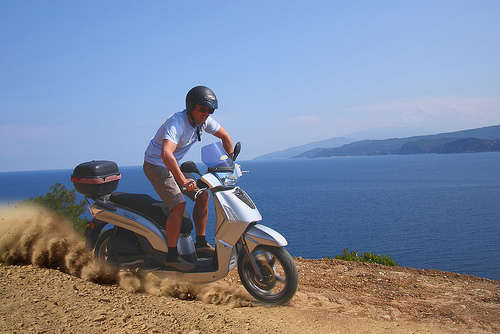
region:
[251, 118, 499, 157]
Mountains next to water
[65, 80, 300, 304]
Man riding a silver scooter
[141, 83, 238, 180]
Man with black helmet wearing a blue shirt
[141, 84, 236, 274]
Man in a blue shirt wearing tan shorts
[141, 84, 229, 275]
Man in tan loafers wearing sunglasses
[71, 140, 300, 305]
Silver moped on a dirt road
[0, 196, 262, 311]
Plume of dirt under a moped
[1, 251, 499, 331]
Dirt road next to the water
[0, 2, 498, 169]
Blue sky behind the man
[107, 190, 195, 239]
Black seat on a silver moped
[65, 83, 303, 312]
man spinning tires on scooter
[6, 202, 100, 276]
dust stirred up from scooter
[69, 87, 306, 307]
man in blue shirt on scooter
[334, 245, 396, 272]
green grass beside dirt road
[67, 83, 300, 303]
man wearing black helmet riding scooter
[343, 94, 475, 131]
white clouds over mountain range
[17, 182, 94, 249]
green tree behind silver scooter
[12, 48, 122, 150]
clear sky over blue ocean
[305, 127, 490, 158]
mountain range by the ocean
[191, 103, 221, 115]
man wear black sunglasses riding scooter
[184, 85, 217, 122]
Black helmet on a man.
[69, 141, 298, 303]
A silver scooter.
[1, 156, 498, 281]
A blue body of water.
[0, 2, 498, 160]
A blue sky.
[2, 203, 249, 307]
All the dirt kicked up into the air.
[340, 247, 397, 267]
Green patch of grass in front of a bike.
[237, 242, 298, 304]
Black front scooter wheel.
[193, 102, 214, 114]
Black sunglasses on a man's face.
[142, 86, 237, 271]
A man in a blue shirt and brown shoes.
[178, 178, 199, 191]
A man's right hand.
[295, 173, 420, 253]
the water is calm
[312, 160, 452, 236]
the water is calm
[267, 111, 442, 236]
the water is calm